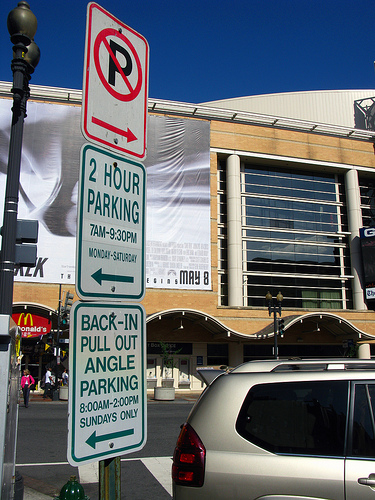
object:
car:
[171, 356, 374, 499]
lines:
[0, 453, 71, 473]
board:
[81, 1, 150, 161]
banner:
[0, 97, 214, 293]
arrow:
[89, 267, 135, 288]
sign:
[76, 142, 146, 301]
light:
[170, 423, 206, 488]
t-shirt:
[45, 371, 52, 384]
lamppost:
[0, 1, 41, 500]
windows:
[217, 158, 374, 311]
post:
[97, 455, 121, 500]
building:
[2, 80, 375, 401]